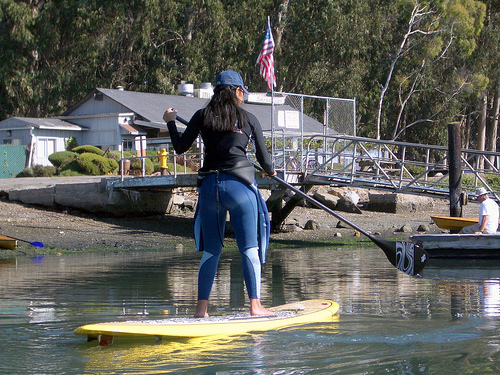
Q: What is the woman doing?
A: Paddleboarding.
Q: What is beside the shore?
A: A walkway.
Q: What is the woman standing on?
A: A surfboard.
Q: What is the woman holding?
A: A paddle.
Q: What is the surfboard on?
A: The water.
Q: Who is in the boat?
A: A man. .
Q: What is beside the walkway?
A: A flag.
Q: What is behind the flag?
A: A house.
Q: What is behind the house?
A: The trees.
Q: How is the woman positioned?
A: Standing.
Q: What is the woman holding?
A: Paddle stick.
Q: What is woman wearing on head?
A: Blue hat.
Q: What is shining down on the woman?
A: Sunlight.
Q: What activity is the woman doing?
A: Paddle boarding.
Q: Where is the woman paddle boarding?
A: Near shore.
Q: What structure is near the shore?
A: Dock.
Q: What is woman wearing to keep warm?
A: Wet suit.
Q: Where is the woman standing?
A: On surfboard.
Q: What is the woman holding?
A: Paddle.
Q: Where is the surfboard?
A: On water.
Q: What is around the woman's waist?
A: Wet suit.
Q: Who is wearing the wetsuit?
A: Young woman.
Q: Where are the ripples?
A: In water.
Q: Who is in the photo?
A: A woman and a man.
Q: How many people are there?
A: 2.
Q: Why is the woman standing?
A: Balancing.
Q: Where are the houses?
A: On the left of the woman.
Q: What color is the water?
A: Blue.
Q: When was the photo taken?
A: Day time.